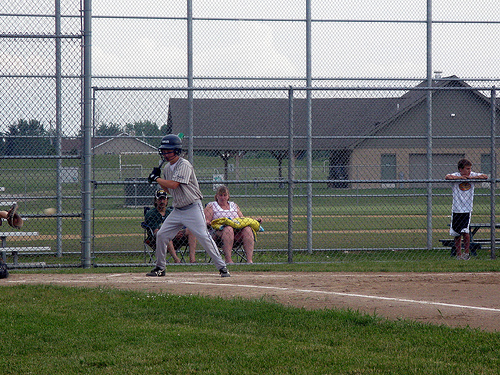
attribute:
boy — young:
[445, 153, 481, 260]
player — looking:
[154, 133, 228, 280]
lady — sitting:
[216, 187, 257, 248]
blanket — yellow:
[230, 218, 256, 228]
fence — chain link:
[291, 104, 320, 191]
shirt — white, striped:
[460, 193, 472, 209]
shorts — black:
[452, 214, 472, 229]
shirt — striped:
[168, 173, 199, 200]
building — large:
[379, 137, 443, 151]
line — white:
[328, 289, 400, 301]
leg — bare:
[225, 234, 233, 260]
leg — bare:
[244, 233, 257, 258]